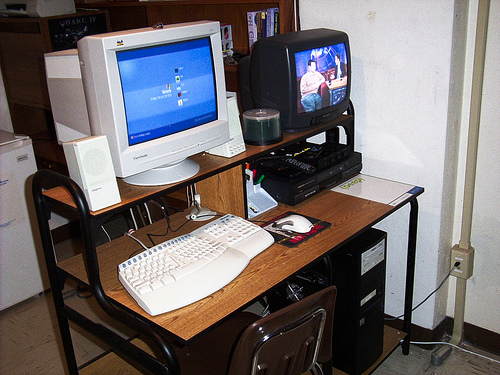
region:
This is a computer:
[128, 41, 238, 336]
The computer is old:
[95, 70, 180, 228]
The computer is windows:
[143, 139, 266, 194]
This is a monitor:
[70, 57, 227, 178]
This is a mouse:
[268, 215, 298, 226]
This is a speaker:
[83, 153, 136, 213]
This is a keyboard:
[122, 161, 250, 347]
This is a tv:
[276, 33, 401, 108]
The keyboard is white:
[136, 227, 221, 272]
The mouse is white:
[267, 209, 345, 281]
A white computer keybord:
[122, 219, 282, 284]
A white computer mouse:
[272, 209, 314, 234]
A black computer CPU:
[340, 241, 385, 373]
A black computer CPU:
[265, 158, 364, 180]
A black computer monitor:
[258, 42, 360, 123]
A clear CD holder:
[241, 106, 286, 141]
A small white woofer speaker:
[63, 142, 127, 201]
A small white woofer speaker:
[217, 89, 246, 154]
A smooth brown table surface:
[307, 198, 374, 233]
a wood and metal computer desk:
[30, 98, 424, 373]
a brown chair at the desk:
[172, 285, 336, 374]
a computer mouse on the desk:
[271, 214, 314, 233]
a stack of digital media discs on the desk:
[242, 108, 284, 145]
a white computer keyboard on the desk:
[117, 212, 274, 315]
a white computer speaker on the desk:
[62, 134, 120, 210]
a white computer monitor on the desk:
[43, 20, 230, 185]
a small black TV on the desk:
[237, 27, 351, 134]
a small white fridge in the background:
[0, 130, 50, 311]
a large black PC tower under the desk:
[265, 227, 385, 374]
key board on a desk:
[123, 242, 275, 312]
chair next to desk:
[260, 290, 350, 365]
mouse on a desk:
[270, 200, 325, 247]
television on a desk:
[275, 31, 360, 118]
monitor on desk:
[111, 0, 233, 172]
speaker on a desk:
[66, 130, 117, 200]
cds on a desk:
[251, 100, 284, 142]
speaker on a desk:
[221, 143, 249, 159]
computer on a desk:
[350, 238, 393, 366]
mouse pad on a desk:
[282, 235, 322, 257]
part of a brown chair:
[175, 287, 340, 372]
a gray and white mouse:
[265, 215, 310, 235]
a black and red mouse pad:
[260, 210, 327, 246]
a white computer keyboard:
[115, 212, 277, 314]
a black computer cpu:
[309, 223, 390, 373]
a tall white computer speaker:
[56, 137, 126, 210]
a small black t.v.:
[237, 27, 354, 130]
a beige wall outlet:
[449, 248, 471, 280]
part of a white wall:
[353, 9, 448, 190]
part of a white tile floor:
[2, 298, 107, 374]